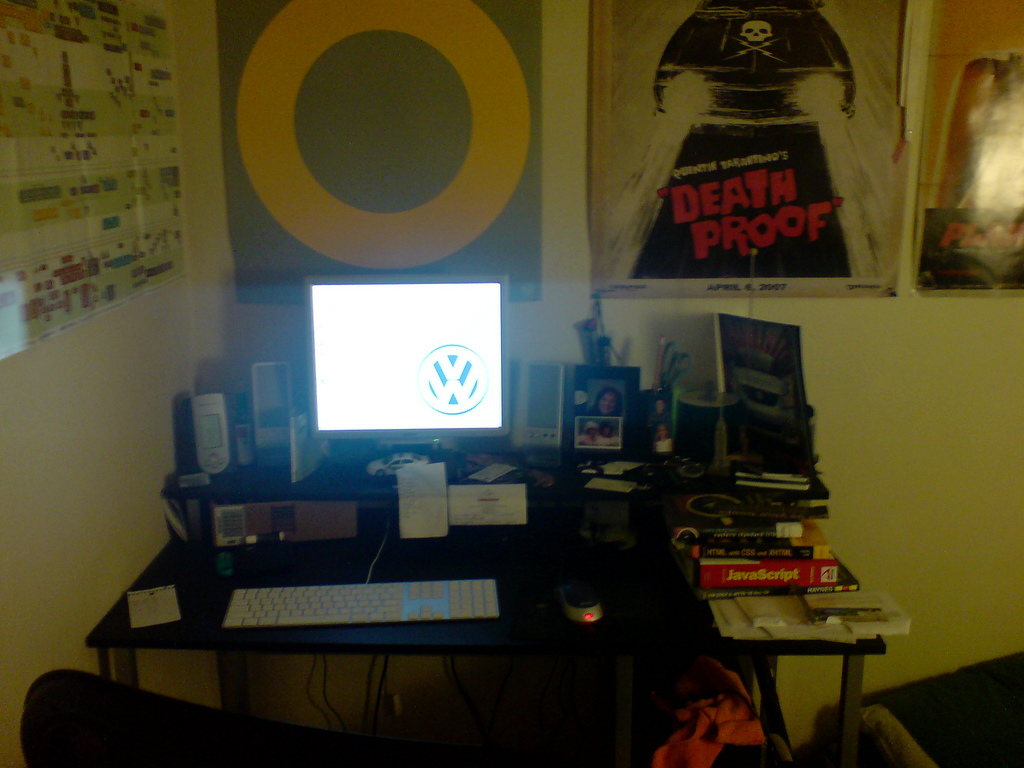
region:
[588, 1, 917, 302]
poster is on a wall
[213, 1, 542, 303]
poster is on a wall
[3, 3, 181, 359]
poster is on a wall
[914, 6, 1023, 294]
poster is on a wall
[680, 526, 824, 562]
game is on a desk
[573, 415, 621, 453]
picture is on a desk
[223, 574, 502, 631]
keyboard on the black desk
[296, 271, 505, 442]
monitor on the black desk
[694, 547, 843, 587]
book on the black desk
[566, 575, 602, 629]
mouse on the black desk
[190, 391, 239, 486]
speaker on the black desk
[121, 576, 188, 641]
keypad on the black desk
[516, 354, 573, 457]
speaker on the black desk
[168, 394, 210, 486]
phone on the black desk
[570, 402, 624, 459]
picture on the black desk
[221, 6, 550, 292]
the circle is yellow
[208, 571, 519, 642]
the keyboard is white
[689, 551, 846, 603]
the book is red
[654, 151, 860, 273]
the letters are red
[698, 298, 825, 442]
the cover of book is black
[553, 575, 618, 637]
the mouse has a red light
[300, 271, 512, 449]
the screen is white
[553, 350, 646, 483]
a picture over the desk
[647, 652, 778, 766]
the backpack is orange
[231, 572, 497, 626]
a white computer keyboard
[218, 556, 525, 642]
a computer keyboard on a desk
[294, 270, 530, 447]
a computer monitor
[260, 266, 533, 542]
a computer monitor on a desk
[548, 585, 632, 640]
a black and silver computer mouse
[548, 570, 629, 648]
a computer mouse with a red light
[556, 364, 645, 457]
a framed picture on a desk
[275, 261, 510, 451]
monitor on small table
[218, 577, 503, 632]
white keyboard on table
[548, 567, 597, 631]
silver mouse on table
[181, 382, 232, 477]
small speaker on tabel mount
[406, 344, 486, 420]
logo on computer screen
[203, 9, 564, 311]
large poster on wall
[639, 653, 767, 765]
orangel cloth under table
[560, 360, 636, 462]
picture in frame on table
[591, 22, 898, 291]
a poster on the wall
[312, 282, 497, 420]
the computer screen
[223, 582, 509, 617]
a white keyboard on the desk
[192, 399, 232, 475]
a white speaker on the desk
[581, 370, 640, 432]
a black picture frame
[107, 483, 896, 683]
a black desk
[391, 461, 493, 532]
papers on the desk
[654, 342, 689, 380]
the handle of scissors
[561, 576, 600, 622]
a computer mouse on the desk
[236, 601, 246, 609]
a key on a keyboard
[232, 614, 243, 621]
a key on a keyboard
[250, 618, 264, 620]
a key on a keyboard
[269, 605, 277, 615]
a key on a keyboard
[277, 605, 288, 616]
a key on a keyboard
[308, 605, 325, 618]
a key on a keyboard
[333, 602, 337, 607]
a key on a keyboard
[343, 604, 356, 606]
a key on a keyboard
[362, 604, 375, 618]
a key on a keyboard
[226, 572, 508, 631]
white keyboard on top of black desk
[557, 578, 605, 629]
black and gray computer mouse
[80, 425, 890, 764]
black desk in the corner of room